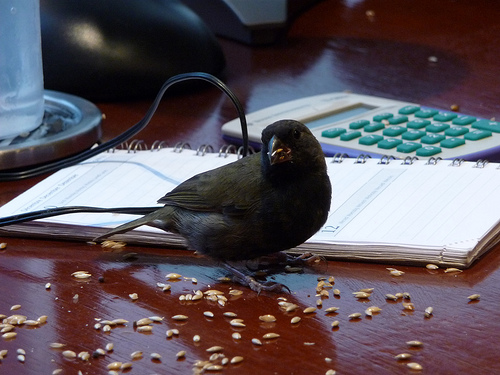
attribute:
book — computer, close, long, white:
[0, 141, 499, 280]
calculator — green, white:
[224, 81, 499, 168]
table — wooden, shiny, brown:
[7, 6, 495, 374]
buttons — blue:
[321, 106, 450, 170]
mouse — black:
[36, 2, 238, 115]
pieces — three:
[394, 336, 425, 368]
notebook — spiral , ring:
[2, 137, 475, 274]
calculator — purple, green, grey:
[214, 87, 470, 163]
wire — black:
[0, 69, 253, 181]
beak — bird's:
[262, 132, 297, 169]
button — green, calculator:
[323, 102, 476, 157]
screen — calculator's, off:
[280, 100, 388, 130]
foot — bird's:
[248, 274, 295, 302]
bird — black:
[35, 118, 337, 291]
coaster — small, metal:
[6, 82, 101, 179]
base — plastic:
[230, 14, 292, 54]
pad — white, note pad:
[1, 123, 473, 261]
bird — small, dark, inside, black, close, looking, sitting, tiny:
[92, 112, 336, 299]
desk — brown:
[7, 2, 471, 372]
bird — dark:
[81, 117, 329, 297]